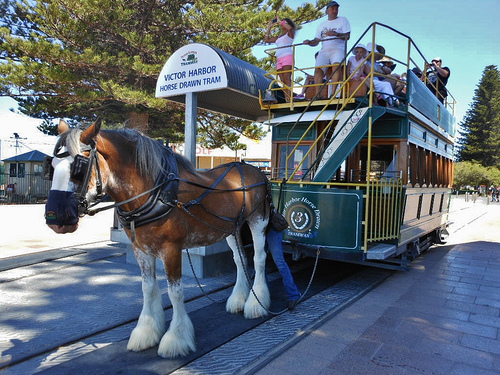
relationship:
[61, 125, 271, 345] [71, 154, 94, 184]
horse with blinders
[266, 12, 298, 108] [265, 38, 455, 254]
woman on top of trolley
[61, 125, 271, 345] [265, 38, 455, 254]
horse pulling tram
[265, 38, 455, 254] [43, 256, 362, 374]
trolley on top of tracks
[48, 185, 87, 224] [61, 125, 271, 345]
mask on front of horse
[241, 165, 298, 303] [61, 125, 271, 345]
person with horse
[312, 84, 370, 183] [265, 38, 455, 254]
stairway leading to tram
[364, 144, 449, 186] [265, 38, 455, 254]
windows on side of trolley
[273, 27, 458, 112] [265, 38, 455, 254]
people atop trolley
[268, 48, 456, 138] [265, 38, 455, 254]
top of a trolley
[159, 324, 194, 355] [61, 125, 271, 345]
foot of horse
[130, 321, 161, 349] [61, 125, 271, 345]
foot of horse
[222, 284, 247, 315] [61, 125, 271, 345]
foot of horse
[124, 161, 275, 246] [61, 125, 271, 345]
body of horse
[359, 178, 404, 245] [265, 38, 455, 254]
door of trolley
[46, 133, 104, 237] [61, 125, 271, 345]
face of horse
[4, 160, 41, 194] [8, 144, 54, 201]
part of building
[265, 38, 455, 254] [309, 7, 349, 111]
trolley with tourist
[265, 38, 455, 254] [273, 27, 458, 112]
trolley with tourist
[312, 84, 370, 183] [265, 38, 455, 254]
stairway on trolley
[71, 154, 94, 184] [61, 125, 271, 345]
blinders on horse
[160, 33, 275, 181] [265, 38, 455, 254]
station for trolley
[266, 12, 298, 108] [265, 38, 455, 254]
woman on trolley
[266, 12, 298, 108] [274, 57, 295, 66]
woman in shorts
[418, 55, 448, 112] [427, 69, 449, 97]
man in shirt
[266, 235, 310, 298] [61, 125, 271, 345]
leg behind horse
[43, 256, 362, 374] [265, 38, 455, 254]
tracks for trolley